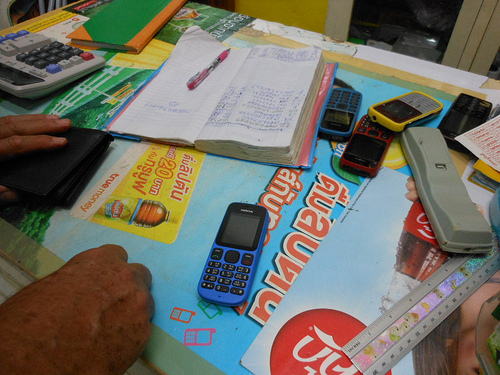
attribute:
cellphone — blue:
[199, 194, 268, 307]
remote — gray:
[397, 121, 495, 256]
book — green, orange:
[59, 0, 194, 56]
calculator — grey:
[0, 27, 107, 102]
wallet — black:
[13, 121, 114, 211]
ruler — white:
[338, 227, 498, 374]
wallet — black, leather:
[10, 157, 84, 202]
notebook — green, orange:
[65, 1, 187, 54]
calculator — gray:
[14, 18, 75, 102]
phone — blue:
[196, 198, 271, 305]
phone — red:
[308, 131, 391, 182]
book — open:
[102, 22, 340, 171]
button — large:
[44, 62, 62, 73]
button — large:
[56, 58, 74, 69]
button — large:
[66, 52, 84, 65]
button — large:
[32, 57, 50, 69]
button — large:
[44, 52, 60, 62]